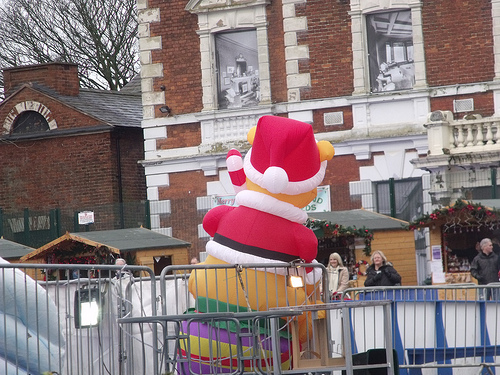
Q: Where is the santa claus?
A: On street.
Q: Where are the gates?
A: Behind santa.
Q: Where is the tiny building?
A: Along street.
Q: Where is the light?
A: On fence.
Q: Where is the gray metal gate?
A: Along the side.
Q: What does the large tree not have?
A: Leaves.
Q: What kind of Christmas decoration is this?
A: A santa.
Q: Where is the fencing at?
A: A christmas display.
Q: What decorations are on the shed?
A: Christmas decorations.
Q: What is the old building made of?
A: Brick.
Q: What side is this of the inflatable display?
A: The back.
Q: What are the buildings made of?
A: Brick.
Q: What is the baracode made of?
A: Metal.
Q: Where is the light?
A: On the baracade.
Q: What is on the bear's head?
A: Santa clause hat.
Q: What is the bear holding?
A: A candy cane.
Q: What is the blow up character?
A: Winnie the pooh.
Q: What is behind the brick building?
A: Bare tree.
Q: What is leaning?
A: Balloon.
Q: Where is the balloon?
A: Sidewalk.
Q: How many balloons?
A: One.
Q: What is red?
A: Hat.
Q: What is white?
A: Window.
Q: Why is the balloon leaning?
A: Wind.